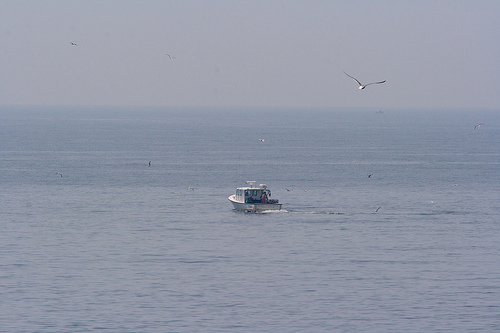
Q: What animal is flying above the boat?
A: A bird.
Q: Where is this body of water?
A: The ocean.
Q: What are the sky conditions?
A: Clear.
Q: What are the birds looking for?
A: Fish.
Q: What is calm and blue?
A: The water.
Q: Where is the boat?
A: Water.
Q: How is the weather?
A: Fair.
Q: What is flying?
A: Seagulls.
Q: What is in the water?
A: Boat.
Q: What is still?
A: Water.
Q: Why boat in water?
A: Floating.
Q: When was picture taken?
A: Daytime.